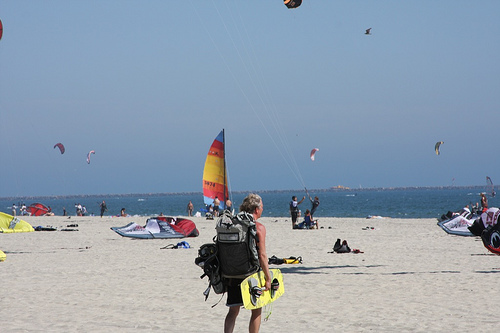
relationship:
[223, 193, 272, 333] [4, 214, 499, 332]
man on beach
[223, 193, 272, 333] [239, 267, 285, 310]
man holding board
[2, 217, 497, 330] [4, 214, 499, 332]
sandy ground on beach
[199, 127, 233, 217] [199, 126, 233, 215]
sailboat has sail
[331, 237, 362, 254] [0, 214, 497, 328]
items sitting on sand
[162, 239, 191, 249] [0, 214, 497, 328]
object sitting on sand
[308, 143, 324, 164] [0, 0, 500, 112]
parasail in sky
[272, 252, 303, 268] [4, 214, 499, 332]
bag left on beach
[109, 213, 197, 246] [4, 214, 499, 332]
vehicle on beach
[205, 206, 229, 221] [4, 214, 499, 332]
sailboat on beach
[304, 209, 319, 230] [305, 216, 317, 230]
person sitting in chair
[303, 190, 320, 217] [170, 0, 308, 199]
boy holding lines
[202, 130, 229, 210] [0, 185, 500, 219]
sail near blue sea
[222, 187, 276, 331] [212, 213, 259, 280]
man wearing backpack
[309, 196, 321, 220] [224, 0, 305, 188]
boy holding lines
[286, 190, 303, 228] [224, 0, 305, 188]
person holding lines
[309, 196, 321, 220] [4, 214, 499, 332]
boy on beach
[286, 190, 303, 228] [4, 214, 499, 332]
person on beach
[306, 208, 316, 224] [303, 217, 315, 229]
person sitting in chair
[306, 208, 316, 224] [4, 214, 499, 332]
person sitting on beach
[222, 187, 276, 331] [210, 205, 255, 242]
man wearing backpack